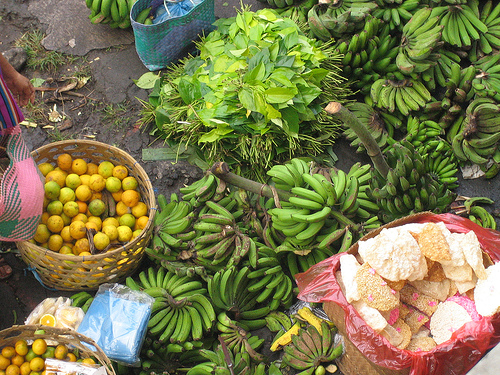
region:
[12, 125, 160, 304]
A basket full of fruit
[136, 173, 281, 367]
Large bundles of green bananas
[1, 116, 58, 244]
Pink and green bag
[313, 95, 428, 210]
Branch from a banana tree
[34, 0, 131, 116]
Broken pieces of concrete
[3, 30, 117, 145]
Muddy ground with a little grass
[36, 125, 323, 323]
Green and yellow fruit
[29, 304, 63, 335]
A lemon cut open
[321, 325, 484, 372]
Red bag lining the inside of a basket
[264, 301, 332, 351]
Two yellow bananas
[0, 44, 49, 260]
person in pink dress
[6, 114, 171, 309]
large wicker basket of fruit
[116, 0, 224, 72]
blue and green handbag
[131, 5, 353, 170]
large bunch of green fruit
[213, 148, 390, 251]
large bunch of green bananas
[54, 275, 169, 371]
blue cloth in plastic bag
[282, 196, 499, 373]
large basket of bread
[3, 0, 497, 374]
large harvest of fruit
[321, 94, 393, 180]
branch of banana tree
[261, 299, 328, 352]
two ripe yellow bananas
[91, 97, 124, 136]
small patch of grass on ground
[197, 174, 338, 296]
many different bananas on ground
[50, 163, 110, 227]
round fruit in basket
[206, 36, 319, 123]
many different leaves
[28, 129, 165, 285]
basket of fruit on ground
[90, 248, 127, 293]
brown basket with yellow fruit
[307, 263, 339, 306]
red plastic on right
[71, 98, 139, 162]
brown dirt under grass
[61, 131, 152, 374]
two baskets of fruit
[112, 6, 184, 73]
blue basket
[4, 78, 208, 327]
a basket of lemons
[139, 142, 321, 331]
bunches of bananas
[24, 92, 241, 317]
lemons and bananas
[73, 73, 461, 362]
bananas on the ground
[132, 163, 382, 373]
green bananas on the ground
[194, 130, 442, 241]
bananas on a branch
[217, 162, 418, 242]
a branch with bananas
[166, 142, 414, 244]
bananas ready to be picked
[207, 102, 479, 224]
green bananas on branches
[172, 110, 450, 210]
banans on green branches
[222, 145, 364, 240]
small green bananas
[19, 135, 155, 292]
brown basket of fruit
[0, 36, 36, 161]
a person's left arm and hand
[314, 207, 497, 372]
red plastic bag lining a basket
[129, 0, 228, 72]
blue shopping bag with two bananas inside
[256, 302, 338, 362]
two yellow bananas lying with the green bananas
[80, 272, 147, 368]
an blue item sealed in clear plastic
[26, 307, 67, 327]
an orange cut into half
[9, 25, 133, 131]
grass growing in the cracks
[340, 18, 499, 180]
a large stack of green bananas